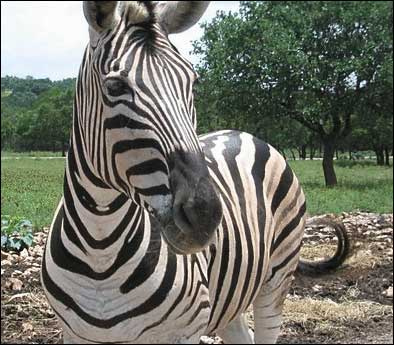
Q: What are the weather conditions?
A: It is clear.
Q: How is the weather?
A: It is clear.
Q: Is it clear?
A: Yes, it is clear.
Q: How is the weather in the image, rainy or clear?
A: It is clear.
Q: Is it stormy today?
A: No, it is clear.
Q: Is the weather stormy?
A: No, it is clear.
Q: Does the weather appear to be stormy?
A: No, it is clear.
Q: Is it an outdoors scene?
A: Yes, it is outdoors.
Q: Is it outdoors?
A: Yes, it is outdoors.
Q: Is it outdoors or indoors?
A: It is outdoors.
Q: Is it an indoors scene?
A: No, it is outdoors.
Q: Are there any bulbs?
A: No, there are no bulbs.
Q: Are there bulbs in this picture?
A: No, there are no bulbs.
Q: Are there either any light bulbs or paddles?
A: No, there are no light bulbs or paddles.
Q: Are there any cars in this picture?
A: No, there are no cars.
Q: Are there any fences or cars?
A: No, there are no cars or fences.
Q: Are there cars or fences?
A: No, there are no cars or fences.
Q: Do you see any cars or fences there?
A: No, there are no cars or fences.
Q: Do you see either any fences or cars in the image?
A: No, there are no cars or fences.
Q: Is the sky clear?
A: Yes, the sky is clear.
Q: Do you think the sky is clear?
A: Yes, the sky is clear.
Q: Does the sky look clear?
A: Yes, the sky is clear.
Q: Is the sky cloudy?
A: No, the sky is clear.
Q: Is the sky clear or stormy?
A: The sky is clear.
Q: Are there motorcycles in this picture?
A: No, there are no motorcycles.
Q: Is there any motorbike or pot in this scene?
A: No, there are no motorcycles or pots.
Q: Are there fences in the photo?
A: No, there are no fences.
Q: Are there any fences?
A: No, there are no fences.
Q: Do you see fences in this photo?
A: No, there are no fences.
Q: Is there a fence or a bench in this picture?
A: No, there are no fences or benches.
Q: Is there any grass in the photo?
A: Yes, there is grass.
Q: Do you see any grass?
A: Yes, there is grass.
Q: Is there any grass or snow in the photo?
A: Yes, there is grass.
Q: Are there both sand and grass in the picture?
A: No, there is grass but no sand.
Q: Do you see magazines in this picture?
A: No, there are no magazines.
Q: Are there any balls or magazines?
A: No, there are no magazines or balls.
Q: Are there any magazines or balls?
A: No, there are no magazines or balls.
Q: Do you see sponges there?
A: No, there are no sponges.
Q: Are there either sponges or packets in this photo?
A: No, there are no sponges or packets.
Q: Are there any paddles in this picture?
A: No, there are no paddles.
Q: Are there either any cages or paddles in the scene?
A: No, there are no paddles or cages.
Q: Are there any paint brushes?
A: No, there are no paint brushes.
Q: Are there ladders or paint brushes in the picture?
A: No, there are no paint brushes or ladders.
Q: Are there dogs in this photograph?
A: No, there are no dogs.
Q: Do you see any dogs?
A: No, there are no dogs.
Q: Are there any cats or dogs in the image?
A: No, there are no dogs or cats.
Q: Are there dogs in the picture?
A: No, there are no dogs.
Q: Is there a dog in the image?
A: No, there are no dogs.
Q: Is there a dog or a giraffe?
A: No, there are no dogs or giraffes.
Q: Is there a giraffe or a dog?
A: No, there are no dogs or giraffes.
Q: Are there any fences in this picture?
A: No, there are no fences.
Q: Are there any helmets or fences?
A: No, there are no fences or helmets.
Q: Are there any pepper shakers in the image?
A: No, there are no pepper shakers.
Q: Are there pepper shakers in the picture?
A: No, there are no pepper shakers.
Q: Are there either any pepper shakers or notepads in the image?
A: No, there are no pepper shakers or notepads.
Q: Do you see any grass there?
A: Yes, there is grass.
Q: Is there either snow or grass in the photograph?
A: Yes, there is grass.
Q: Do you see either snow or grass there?
A: Yes, there is grass.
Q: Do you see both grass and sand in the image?
A: No, there is grass but no sand.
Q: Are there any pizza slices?
A: No, there are no pizza slices.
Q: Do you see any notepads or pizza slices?
A: No, there are no pizza slices or notepads.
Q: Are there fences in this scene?
A: No, there are no fences.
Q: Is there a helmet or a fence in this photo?
A: No, there are no fences or helmets.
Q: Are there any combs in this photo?
A: No, there are no combs.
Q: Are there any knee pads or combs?
A: No, there are no combs or knee pads.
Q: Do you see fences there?
A: No, there are no fences.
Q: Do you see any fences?
A: No, there are no fences.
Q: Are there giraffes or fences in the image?
A: No, there are no fences or giraffes.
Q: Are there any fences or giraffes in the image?
A: No, there are no fences or giraffes.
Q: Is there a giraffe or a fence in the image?
A: No, there are no fences or giraffes.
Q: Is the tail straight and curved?
A: No, the tail is curved but curly.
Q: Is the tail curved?
A: Yes, the tail is curved.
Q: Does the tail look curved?
A: Yes, the tail is curved.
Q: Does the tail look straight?
A: No, the tail is curved.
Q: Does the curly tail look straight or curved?
A: The tail is curved.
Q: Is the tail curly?
A: Yes, the tail is curly.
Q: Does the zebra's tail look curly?
A: Yes, the tail is curly.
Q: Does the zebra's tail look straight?
A: No, the tail is curly.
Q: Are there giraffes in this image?
A: No, there are no giraffes.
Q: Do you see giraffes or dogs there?
A: No, there are no giraffes or dogs.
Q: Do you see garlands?
A: No, there are no garlands.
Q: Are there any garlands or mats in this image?
A: No, there are no garlands or mats.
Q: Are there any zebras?
A: Yes, there is a zebra.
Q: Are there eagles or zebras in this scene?
A: Yes, there is a zebra.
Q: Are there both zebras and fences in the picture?
A: No, there is a zebra but no fences.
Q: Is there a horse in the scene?
A: No, there are no horses.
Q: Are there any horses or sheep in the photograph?
A: No, there are no horses or sheep.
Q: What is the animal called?
A: The animal is a zebra.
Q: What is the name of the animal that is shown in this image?
A: The animal is a zebra.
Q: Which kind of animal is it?
A: The animal is a zebra.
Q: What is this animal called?
A: That is a zebra.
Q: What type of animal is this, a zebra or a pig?
A: That is a zebra.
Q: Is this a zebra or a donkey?
A: This is a zebra.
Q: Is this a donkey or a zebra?
A: This is a zebra.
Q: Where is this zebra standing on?
A: The zebra is standing on the dirt.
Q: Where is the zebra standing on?
A: The zebra is standing on the dirt.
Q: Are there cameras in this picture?
A: Yes, there is a camera.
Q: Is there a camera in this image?
A: Yes, there is a camera.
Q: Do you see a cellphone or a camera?
A: Yes, there is a camera.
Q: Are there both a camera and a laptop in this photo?
A: No, there is a camera but no laptops.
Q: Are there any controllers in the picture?
A: No, there are no controllers.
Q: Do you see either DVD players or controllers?
A: No, there are no controllers or DVD players.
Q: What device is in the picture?
A: The device is a camera.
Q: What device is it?
A: The device is a camera.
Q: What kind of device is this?
A: That is a camera.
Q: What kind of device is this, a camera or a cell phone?
A: That is a camera.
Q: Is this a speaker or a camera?
A: This is a camera.